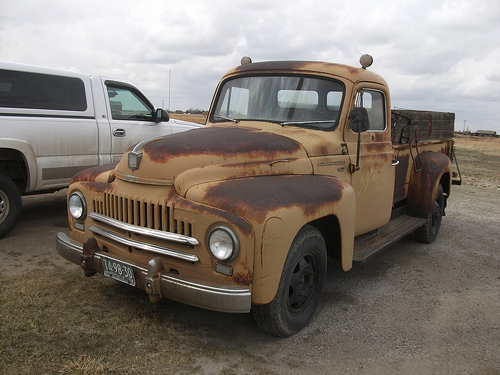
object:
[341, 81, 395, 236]
door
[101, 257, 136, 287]
license plate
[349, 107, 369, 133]
mirror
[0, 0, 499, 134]
sky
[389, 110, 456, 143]
bed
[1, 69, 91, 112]
window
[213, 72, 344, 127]
windshield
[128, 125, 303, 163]
mark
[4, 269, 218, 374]
grass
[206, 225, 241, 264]
headlight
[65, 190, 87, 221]
headlight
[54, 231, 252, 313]
bumper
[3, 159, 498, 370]
ground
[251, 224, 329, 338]
tire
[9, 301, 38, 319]
flower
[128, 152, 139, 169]
light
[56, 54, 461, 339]
car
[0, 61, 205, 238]
car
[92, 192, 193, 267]
grill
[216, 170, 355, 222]
empty plate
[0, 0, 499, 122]
cloud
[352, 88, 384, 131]
window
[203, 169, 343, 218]
spot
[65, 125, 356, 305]
hood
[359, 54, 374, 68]
light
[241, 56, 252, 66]
light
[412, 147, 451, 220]
part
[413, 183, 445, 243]
wheel